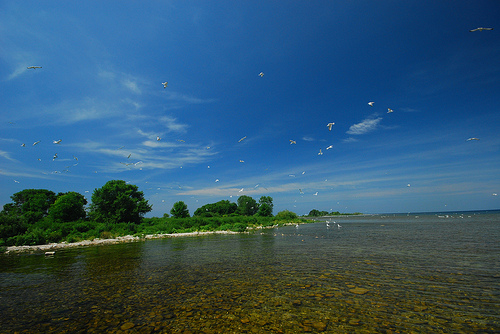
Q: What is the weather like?
A: It is cloudy.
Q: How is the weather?
A: It is cloudy.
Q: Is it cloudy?
A: Yes, it is cloudy.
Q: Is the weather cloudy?
A: Yes, it is cloudy.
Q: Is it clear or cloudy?
A: It is cloudy.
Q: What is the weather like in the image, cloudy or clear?
A: It is cloudy.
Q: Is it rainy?
A: No, it is cloudy.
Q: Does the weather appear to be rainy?
A: No, it is cloudy.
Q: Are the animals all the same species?
A: Yes, all the animals are birds.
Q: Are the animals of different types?
A: No, all the animals are birds.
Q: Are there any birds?
A: Yes, there are birds.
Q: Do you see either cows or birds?
A: Yes, there are birds.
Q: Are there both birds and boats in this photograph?
A: No, there are birds but no boats.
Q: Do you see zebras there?
A: No, there are no zebras.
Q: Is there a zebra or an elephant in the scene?
A: No, there are no zebras or elephants.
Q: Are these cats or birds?
A: These are birds.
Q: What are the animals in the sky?
A: The animals are birds.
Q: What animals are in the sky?
A: The animals are birds.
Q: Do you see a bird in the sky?
A: Yes, there are birds in the sky.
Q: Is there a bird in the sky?
A: Yes, there are birds in the sky.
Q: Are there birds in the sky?
A: Yes, there are birds in the sky.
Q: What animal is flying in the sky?
A: The birds are flying in the sky.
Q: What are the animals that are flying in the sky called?
A: The animals are birds.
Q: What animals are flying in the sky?
A: The animals are birds.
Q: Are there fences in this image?
A: No, there are no fences.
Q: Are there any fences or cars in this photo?
A: No, there are no fences or cars.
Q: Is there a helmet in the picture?
A: No, there are no helmets.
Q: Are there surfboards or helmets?
A: No, there are no helmets or surfboards.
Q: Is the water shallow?
A: Yes, the water is shallow.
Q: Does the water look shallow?
A: Yes, the water is shallow.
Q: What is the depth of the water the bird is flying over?
A: The water is shallow.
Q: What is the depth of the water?
A: The water is shallow.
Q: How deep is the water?
A: The water is shallow.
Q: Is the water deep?
A: No, the water is shallow.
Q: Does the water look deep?
A: No, the water is shallow.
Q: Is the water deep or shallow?
A: The water is shallow.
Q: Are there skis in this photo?
A: No, there are no skis.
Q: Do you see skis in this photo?
A: No, there are no skis.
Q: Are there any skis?
A: No, there are no skis.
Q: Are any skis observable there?
A: No, there are no skis.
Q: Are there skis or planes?
A: No, there are no skis or planes.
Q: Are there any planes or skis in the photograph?
A: No, there are no skis or planes.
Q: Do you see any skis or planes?
A: No, there are no skis or planes.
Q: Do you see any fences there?
A: No, there are no fences.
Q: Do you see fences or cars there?
A: No, there are no fences or cars.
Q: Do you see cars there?
A: No, there are no cars.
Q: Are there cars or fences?
A: No, there are no cars or fences.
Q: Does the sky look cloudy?
A: Yes, the sky is cloudy.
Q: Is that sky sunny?
A: No, the sky is cloudy.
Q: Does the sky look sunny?
A: No, the sky is cloudy.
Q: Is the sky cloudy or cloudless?
A: The sky is cloudy.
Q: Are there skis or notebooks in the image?
A: No, there are no skis or notebooks.